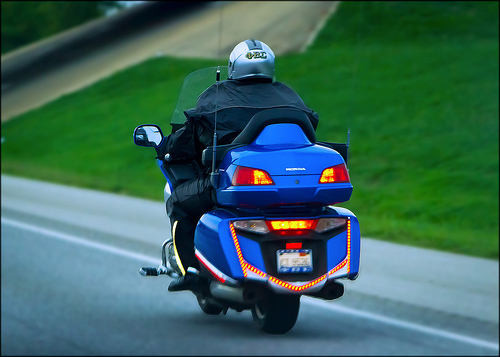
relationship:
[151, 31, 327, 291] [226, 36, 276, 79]
man wearing helmet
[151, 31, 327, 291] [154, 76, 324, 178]
man wearing jacket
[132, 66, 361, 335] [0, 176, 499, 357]
motorcycle on ground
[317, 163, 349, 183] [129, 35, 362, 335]
light on motorcycle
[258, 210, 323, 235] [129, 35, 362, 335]
light on motorcycle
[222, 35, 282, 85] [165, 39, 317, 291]
helmet on man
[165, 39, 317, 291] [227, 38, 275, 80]
man wearing helmet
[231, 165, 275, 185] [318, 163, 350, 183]
light has light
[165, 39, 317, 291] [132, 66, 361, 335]
man riding motorcycle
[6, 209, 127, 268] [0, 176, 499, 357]
line painted on ground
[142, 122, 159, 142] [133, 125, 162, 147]
reflection visible in mirror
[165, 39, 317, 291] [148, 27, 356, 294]
man wearing jacket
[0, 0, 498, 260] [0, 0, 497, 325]
grass growing on hill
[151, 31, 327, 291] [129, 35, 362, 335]
man riding motorcycle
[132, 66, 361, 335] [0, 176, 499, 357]
motorcycle going down ground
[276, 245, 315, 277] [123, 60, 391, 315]
license plate attached to motorcycle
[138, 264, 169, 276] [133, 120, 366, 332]
footrest attached to motorcyle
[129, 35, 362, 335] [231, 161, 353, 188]
motorcycle has brake lights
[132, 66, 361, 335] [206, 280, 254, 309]
motorcycle has muffler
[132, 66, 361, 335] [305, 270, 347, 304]
motorcycle has muffler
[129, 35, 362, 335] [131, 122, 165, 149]
motorcycle has mirror